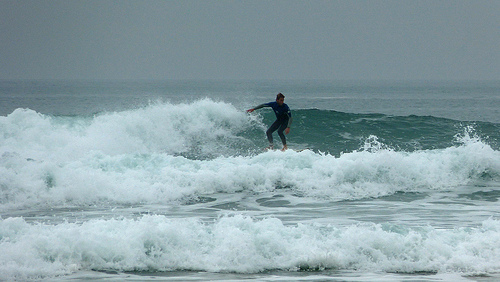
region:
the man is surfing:
[165, 47, 423, 257]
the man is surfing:
[219, 60, 381, 207]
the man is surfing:
[199, 62, 311, 229]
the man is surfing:
[200, 61, 379, 208]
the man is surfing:
[217, 89, 341, 264]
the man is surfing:
[227, 85, 310, 219]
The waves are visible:
[104, 106, 234, 256]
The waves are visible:
[122, 155, 287, 280]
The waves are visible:
[161, 174, 255, 271]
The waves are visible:
[68, 53, 285, 264]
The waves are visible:
[146, 30, 251, 260]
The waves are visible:
[244, 218, 305, 264]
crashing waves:
[53, 174, 413, 252]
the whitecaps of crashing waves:
[71, 185, 476, 270]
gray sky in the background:
[71, 5, 473, 78]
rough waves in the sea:
[11, 87, 497, 218]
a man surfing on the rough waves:
[225, 70, 327, 165]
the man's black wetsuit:
[245, 87, 305, 157]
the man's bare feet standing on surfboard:
[251, 137, 302, 164]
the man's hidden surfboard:
[254, 136, 301, 175]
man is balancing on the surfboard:
[230, 82, 302, 167]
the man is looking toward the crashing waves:
[231, 80, 309, 173]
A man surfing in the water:
[243, 90, 293, 152]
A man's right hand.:
[244, 107, 256, 114]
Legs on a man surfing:
[261, 121, 288, 145]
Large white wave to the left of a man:
[122, 94, 247, 149]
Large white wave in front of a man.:
[243, 148, 325, 194]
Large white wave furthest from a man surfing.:
[2, 209, 499, 271]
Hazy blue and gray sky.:
[0, 1, 495, 80]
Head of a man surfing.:
[272, 91, 286, 104]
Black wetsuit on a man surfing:
[258, 102, 290, 144]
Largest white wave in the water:
[2, 108, 114, 207]